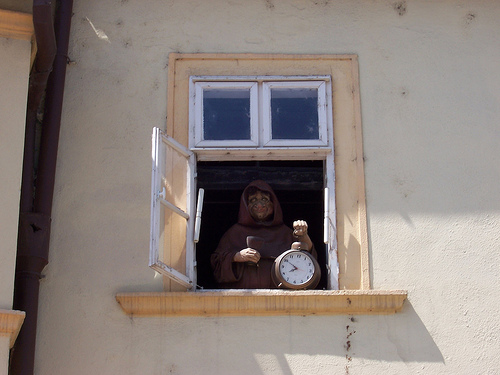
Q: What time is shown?
A: 7:50.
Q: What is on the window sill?
A: A clock.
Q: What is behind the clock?
A: A mannequin.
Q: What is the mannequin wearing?
A: A brown robe.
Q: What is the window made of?
A: Glass.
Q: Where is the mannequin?
A: Behind the clock.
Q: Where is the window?
A: On the building.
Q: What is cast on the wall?
A: Shadows.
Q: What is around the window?
A: A white window frame.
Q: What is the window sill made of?
A: Wood.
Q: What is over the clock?
A: The hand of the mannequin.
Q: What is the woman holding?
A: Clock.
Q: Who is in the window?
A: A lady.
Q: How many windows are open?
A: 1.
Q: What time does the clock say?
A: 7:50.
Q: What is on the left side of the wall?
A: Drain.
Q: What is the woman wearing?
A: Robe.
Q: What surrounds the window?
A: Wood.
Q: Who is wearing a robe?
A: A lady.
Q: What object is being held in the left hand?
A: Clock.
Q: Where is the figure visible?
A: In the window.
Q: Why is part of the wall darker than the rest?
A: It's in shadow.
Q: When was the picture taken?
A: Daytime.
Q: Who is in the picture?
A: Statue.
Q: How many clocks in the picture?
A: One.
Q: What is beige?
A: House walls.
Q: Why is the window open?
A: To display the statue.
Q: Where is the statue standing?
A: In the window.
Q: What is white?
A: Window pane.